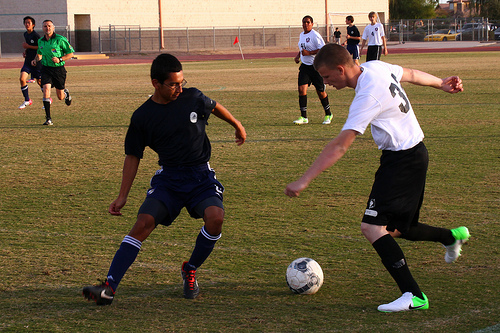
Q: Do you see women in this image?
A: No, there are no women.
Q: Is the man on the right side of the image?
A: Yes, the man is on the right of the image.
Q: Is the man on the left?
A: No, the man is on the right of the image.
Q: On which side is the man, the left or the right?
A: The man is on the right of the image.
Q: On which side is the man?
A: The man is on the right of the image.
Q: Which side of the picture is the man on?
A: The man is on the right of the image.